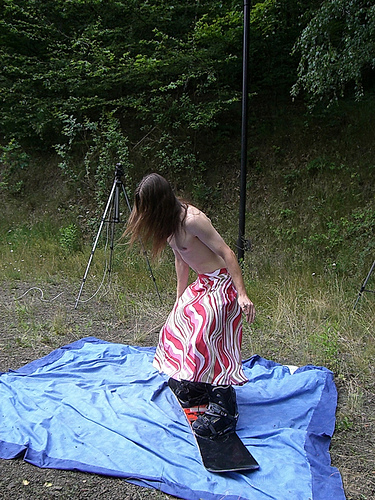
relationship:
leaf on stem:
[119, 140, 123, 145] [112, 128, 123, 147]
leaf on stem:
[91, 162, 109, 177] [93, 151, 98, 165]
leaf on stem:
[97, 143, 106, 151] [130, 120, 162, 139]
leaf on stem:
[110, 126, 113, 128] [98, 106, 110, 139]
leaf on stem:
[166, 81, 177, 89] [91, 77, 215, 97]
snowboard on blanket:
[167, 375, 260, 473] [5, 332, 369, 494]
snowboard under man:
[167, 375, 260, 473] [118, 171, 256, 438]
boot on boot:
[196, 385, 241, 455] [192, 385, 240, 442]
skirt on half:
[172, 285, 227, 340] [166, 271, 283, 396]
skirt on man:
[172, 285, 227, 340] [131, 172, 207, 259]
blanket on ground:
[5, 332, 369, 494] [330, 433, 372, 494]